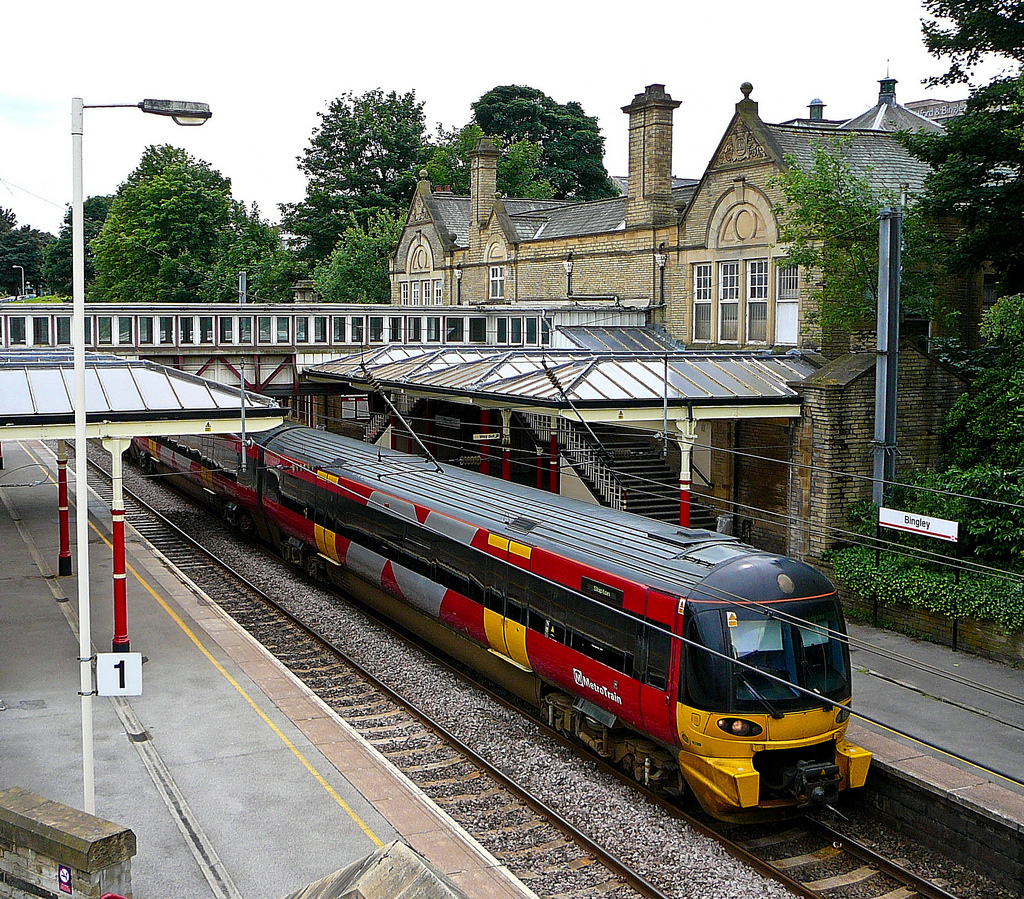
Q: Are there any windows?
A: Yes, there is a window.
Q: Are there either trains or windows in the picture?
A: Yes, there is a window.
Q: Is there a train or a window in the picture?
A: Yes, there is a window.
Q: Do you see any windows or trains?
A: Yes, there is a window.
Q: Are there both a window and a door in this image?
A: Yes, there are both a window and a door.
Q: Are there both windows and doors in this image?
A: Yes, there are both a window and a door.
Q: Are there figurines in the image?
A: No, there are no figurines.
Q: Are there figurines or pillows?
A: No, there are no figurines or pillows.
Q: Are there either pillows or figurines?
A: No, there are no figurines or pillows.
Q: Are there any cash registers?
A: No, there are no cash registers.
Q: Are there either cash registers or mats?
A: No, there are no cash registers or mats.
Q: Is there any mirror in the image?
A: No, there are no mirrors.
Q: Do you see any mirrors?
A: No, there are no mirrors.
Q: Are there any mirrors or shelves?
A: No, there are no mirrors or shelves.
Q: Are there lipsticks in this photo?
A: No, there are no lipsticks.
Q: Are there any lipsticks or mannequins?
A: No, there are no lipsticks or mannequins.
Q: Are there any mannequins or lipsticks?
A: No, there are no lipsticks or mannequins.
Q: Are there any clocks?
A: No, there are no clocks.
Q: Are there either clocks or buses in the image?
A: No, there are no clocks or buses.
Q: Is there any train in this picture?
A: Yes, there is a train.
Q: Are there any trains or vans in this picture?
A: Yes, there is a train.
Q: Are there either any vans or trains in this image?
A: Yes, there is a train.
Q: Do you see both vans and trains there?
A: No, there is a train but no vans.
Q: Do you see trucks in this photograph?
A: No, there are no trucks.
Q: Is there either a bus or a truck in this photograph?
A: No, there are no trucks or buses.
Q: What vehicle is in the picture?
A: The vehicle is a train.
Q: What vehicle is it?
A: The vehicle is a train.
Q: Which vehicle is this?
A: This is a train.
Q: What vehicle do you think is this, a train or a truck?
A: This is a train.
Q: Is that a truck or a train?
A: That is a train.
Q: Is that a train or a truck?
A: That is a train.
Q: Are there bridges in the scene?
A: Yes, there is a bridge.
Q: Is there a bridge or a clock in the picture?
A: Yes, there is a bridge.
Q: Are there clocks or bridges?
A: Yes, there is a bridge.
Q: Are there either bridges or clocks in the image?
A: Yes, there is a bridge.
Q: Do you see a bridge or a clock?
A: Yes, there is a bridge.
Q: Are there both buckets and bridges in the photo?
A: No, there is a bridge but no buckets.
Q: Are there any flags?
A: No, there are no flags.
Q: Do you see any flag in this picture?
A: No, there are no flags.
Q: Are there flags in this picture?
A: No, there are no flags.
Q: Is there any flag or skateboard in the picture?
A: No, there are no flags or skateboards.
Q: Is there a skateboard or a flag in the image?
A: No, there are no flags or skateboards.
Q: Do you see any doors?
A: Yes, there is a door.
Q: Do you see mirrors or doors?
A: Yes, there is a door.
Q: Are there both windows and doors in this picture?
A: Yes, there are both a door and a window.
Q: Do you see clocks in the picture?
A: No, there are no clocks.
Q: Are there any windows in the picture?
A: Yes, there are windows.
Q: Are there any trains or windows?
A: Yes, there are windows.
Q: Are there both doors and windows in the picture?
A: Yes, there are both windows and a door.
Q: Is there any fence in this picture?
A: No, there are no fences.